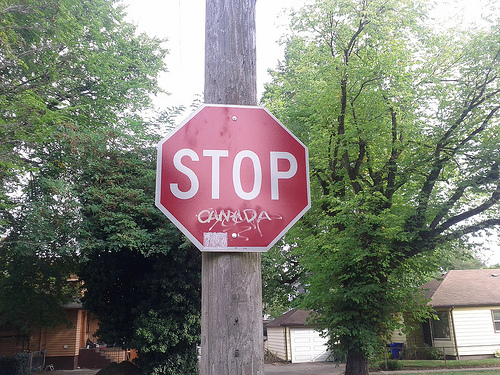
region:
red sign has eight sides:
[156, 102, 310, 252]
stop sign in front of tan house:
[151, 102, 309, 254]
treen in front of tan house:
[256, 95, 497, 371]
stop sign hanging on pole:
[155, 105, 311, 250]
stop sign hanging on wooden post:
[153, 101, 309, 251]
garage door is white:
[287, 326, 332, 362]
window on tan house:
[428, 310, 449, 340]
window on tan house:
[490, 308, 496, 331]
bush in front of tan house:
[400, 342, 447, 357]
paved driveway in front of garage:
[263, 356, 345, 373]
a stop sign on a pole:
[155, 100, 317, 261]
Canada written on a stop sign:
[195, 205, 273, 225]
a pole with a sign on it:
[194, 3, 284, 373]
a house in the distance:
[403, 262, 499, 357]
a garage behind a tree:
[268, 294, 350, 370]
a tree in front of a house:
[301, 23, 498, 358]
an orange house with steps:
[0, 249, 139, 374]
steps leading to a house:
[74, 343, 123, 369]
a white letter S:
[170, 144, 201, 199]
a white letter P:
[266, 147, 302, 204]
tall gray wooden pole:
[185, 276, 292, 356]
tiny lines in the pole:
[222, 311, 260, 369]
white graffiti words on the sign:
[192, 202, 289, 232]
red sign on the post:
[132, 93, 323, 264]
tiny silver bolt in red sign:
[226, 113, 247, 125]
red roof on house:
[428, 262, 480, 301]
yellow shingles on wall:
[39, 325, 77, 343]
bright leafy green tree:
[316, 114, 417, 251]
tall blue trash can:
[381, 338, 418, 363]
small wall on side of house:
[71, 335, 131, 367]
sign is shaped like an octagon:
[153, 99, 311, 246]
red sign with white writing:
[158, 100, 313, 250]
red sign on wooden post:
[200, 3, 262, 373]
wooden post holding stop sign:
[202, 0, 263, 372]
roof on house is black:
[266, 268, 493, 373]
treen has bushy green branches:
[222, 2, 496, 372]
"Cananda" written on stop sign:
[192, 202, 279, 229]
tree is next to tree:
[76, 139, 198, 370]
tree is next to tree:
[258, 3, 496, 373]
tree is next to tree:
[0, 0, 175, 240]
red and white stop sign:
[156, 104, 308, 251]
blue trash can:
[386, 342, 404, 359]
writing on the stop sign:
[197, 205, 272, 226]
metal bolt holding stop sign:
[232, 113, 237, 121]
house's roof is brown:
[417, 268, 497, 308]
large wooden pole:
[197, 0, 260, 370]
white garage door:
[291, 327, 331, 362]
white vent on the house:
[61, 344, 68, 351]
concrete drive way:
[267, 360, 348, 373]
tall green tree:
[278, 6, 497, 370]